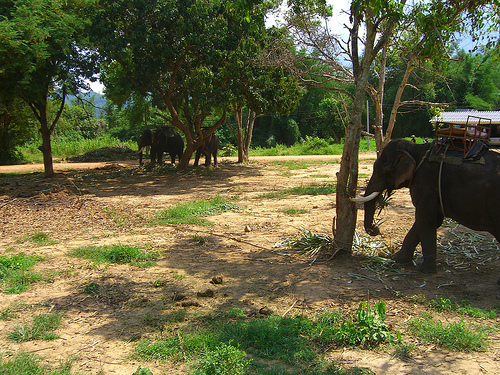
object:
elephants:
[137, 127, 185, 167]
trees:
[97, 0, 305, 170]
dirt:
[0, 158, 500, 375]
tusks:
[348, 192, 379, 203]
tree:
[295, 0, 402, 252]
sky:
[262, 0, 500, 79]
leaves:
[402, 33, 408, 37]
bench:
[434, 114, 492, 158]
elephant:
[351, 138, 500, 274]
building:
[428, 108, 500, 145]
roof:
[429, 109, 500, 123]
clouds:
[262, 0, 382, 68]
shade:
[143, 160, 220, 170]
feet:
[193, 164, 198, 167]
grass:
[0, 348, 74, 375]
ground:
[0, 156, 500, 375]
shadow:
[36, 232, 500, 375]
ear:
[392, 148, 417, 190]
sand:
[170, 226, 248, 264]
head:
[350, 138, 417, 236]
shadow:
[0, 163, 263, 199]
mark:
[345, 173, 350, 192]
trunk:
[363, 170, 387, 236]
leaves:
[387, 197, 394, 201]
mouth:
[379, 186, 394, 197]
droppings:
[197, 288, 214, 298]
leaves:
[309, 250, 322, 266]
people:
[411, 134, 417, 143]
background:
[0, 0, 500, 149]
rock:
[244, 225, 252, 232]